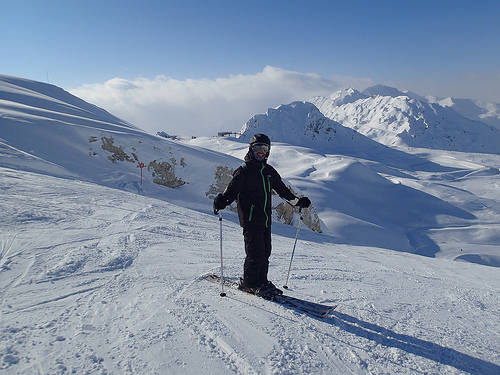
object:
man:
[214, 131, 311, 295]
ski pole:
[283, 208, 305, 291]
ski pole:
[215, 209, 227, 299]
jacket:
[219, 159, 300, 230]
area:
[1, 69, 499, 374]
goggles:
[250, 142, 270, 152]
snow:
[0, 169, 499, 375]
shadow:
[311, 309, 499, 375]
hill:
[234, 98, 378, 155]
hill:
[309, 81, 493, 147]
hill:
[1, 70, 218, 192]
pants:
[240, 222, 273, 282]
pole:
[139, 162, 144, 190]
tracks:
[200, 267, 342, 320]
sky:
[1, 1, 499, 116]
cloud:
[63, 64, 375, 137]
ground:
[0, 168, 498, 373]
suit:
[221, 162, 298, 283]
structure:
[214, 130, 246, 141]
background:
[0, 119, 499, 160]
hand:
[212, 191, 229, 216]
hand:
[294, 194, 311, 211]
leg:
[238, 224, 267, 286]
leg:
[260, 227, 273, 285]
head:
[248, 132, 270, 162]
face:
[252, 141, 268, 161]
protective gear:
[248, 133, 276, 149]